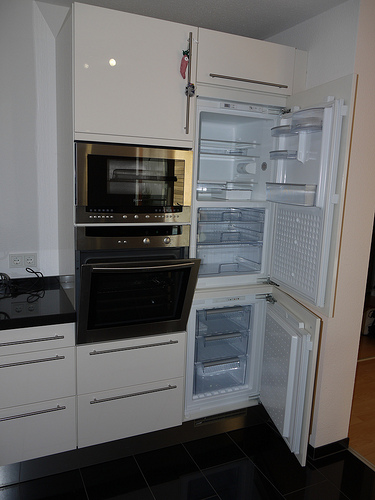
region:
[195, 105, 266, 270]
The inside of a refrigerator.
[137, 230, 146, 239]
A knob on the oven.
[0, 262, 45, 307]
Cord on the counter.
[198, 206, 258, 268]
Shelves inside the refrigerator.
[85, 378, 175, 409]
A handle on a drawer.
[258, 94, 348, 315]
A open door on the refrigerator.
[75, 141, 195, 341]
A stainless steel oven.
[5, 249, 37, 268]
A white wall socket.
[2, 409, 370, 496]
The black tile floor.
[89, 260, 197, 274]
Handle on the oven.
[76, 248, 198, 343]
open oven door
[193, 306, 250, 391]
three clear plastic drawers in the freezer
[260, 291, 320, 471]
open freezer door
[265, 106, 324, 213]
clear plastic trays in the refrigerator door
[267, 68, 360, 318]
open refrigerator door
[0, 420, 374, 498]
shiny black tile floor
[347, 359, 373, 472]
wood floor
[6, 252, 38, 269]
two white power outlets in a wall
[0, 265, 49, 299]
tangled black cords on a counter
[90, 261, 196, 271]
silver metal handle on an oven door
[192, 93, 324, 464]
refrigerators with open doors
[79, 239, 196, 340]
silver oven with open door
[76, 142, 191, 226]
silver and black microwave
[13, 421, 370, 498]
black tile of kitchen floor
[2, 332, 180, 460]
white kitchen cabinets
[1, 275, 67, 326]
black countertop next to oven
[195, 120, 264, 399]
shelves and drawers in fridges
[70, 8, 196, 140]
cabinet above the microwave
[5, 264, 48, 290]
black cord on the countertop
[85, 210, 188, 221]
buttons on the microwave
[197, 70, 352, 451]
a new white refrigerator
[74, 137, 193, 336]
a new silver oven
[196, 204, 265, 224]
a shelf in a refrigerator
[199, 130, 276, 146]
a shelf in a refrigerator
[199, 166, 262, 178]
a shelf in a refrigerator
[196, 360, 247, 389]
a shelf in a refrigerator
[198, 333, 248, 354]
a shelf in a refrigerator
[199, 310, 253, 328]
a shelf in a refrigerator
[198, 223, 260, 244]
a shelf in a refrigerator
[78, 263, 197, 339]
the door of an oven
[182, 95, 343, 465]
White refrigerator with opened doors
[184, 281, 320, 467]
Bottom open door to the freezer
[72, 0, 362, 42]
Ceiling above the refrigerator and stove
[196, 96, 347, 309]
top portion of the refrigerator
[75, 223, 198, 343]
Black stove built into the wall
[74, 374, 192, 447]
Bottom drawer under the stove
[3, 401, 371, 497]
Dark floor that refrigerator and cabinets are setting on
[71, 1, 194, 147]
Top cabinet over the stove and microwave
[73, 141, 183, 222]
Microwave installed over the oven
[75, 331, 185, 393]
The drawer under the over